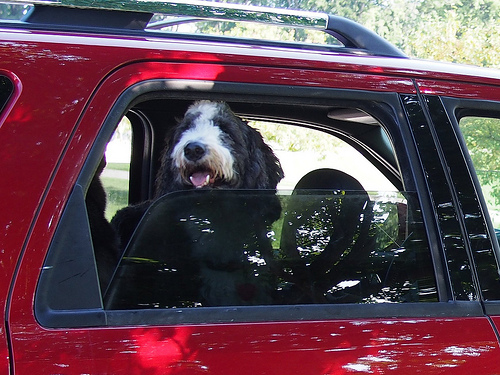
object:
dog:
[110, 99, 294, 306]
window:
[101, 94, 450, 307]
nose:
[183, 142, 203, 161]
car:
[0, 0, 495, 372]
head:
[165, 99, 247, 190]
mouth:
[186, 168, 218, 191]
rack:
[0, 0, 407, 62]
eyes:
[218, 124, 234, 137]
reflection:
[274, 222, 390, 287]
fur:
[235, 145, 265, 179]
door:
[13, 57, 489, 374]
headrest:
[270, 167, 374, 280]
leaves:
[452, 16, 473, 42]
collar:
[199, 254, 254, 273]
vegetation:
[397, 7, 440, 53]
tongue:
[192, 171, 207, 186]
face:
[175, 115, 229, 175]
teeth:
[189, 174, 210, 188]